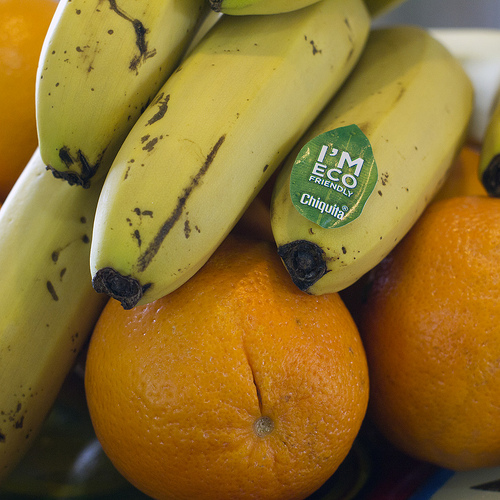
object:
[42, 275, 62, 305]
spot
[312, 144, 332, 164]
i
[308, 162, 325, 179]
letter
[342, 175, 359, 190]
letter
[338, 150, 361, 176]
letter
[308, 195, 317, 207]
letter h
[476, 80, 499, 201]
banana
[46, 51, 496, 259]
banana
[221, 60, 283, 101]
skin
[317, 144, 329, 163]
letter i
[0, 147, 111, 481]
fruit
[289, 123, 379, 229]
sticker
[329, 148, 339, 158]
aprostrophe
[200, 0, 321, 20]
banana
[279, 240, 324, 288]
end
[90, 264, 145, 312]
end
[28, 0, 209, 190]
banana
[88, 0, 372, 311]
banana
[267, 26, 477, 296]
banana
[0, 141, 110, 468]
banana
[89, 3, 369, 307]
fruit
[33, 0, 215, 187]
fruit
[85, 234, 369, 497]
fruit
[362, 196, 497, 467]
fruit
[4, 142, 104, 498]
fruit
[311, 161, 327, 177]
e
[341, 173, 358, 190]
lettering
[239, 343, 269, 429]
creases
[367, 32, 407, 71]
shadow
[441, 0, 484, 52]
background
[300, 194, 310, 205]
lettering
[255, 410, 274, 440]
navel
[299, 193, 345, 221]
word